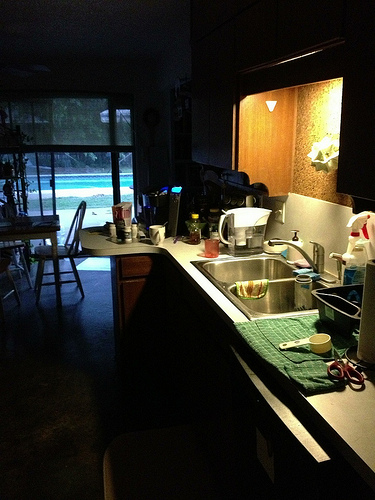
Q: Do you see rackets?
A: No, there are no rackets.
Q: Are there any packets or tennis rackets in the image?
A: No, there are no tennis rackets or packets.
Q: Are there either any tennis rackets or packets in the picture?
A: No, there are no tennis rackets or packets.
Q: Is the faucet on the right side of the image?
A: Yes, the faucet is on the right of the image.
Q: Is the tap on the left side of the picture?
A: No, the tap is on the right of the image.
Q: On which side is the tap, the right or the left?
A: The tap is on the right of the image.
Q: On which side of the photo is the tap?
A: The tap is on the right of the image.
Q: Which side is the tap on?
A: The tap is on the right of the image.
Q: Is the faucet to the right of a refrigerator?
A: No, the faucet is to the right of the cup.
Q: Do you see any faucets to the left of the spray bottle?
A: Yes, there is a faucet to the left of the spray bottle.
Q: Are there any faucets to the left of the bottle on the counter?
A: Yes, there is a faucet to the left of the spray bottle.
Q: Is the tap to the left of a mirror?
A: No, the tap is to the left of the spray bottle.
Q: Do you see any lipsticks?
A: No, there are no lipsticks.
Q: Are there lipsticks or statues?
A: No, there are no lipsticks or statues.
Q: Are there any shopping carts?
A: No, there are no shopping carts.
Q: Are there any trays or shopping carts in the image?
A: No, there are no shopping carts or trays.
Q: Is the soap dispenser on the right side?
A: Yes, the soap dispenser is on the right of the image.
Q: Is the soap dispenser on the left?
A: No, the soap dispenser is on the right of the image.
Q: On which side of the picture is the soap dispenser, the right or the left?
A: The soap dispenser is on the right of the image.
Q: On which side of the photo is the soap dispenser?
A: The soap dispenser is on the right of the image.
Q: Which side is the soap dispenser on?
A: The soap dispenser is on the right of the image.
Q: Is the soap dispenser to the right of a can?
A: No, the soap dispenser is to the right of the cup.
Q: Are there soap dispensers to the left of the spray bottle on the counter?
A: Yes, there is a soap dispenser to the left of the spray bottle.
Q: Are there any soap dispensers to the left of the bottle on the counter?
A: Yes, there is a soap dispenser to the left of the spray bottle.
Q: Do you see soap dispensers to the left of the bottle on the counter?
A: Yes, there is a soap dispenser to the left of the spray bottle.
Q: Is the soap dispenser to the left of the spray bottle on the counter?
A: Yes, the soap dispenser is to the left of the spray bottle.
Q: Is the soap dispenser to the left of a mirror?
A: No, the soap dispenser is to the left of the spray bottle.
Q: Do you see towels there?
A: Yes, there is a towel.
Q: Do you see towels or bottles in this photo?
A: Yes, there is a towel.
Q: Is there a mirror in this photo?
A: No, there are no mirrors.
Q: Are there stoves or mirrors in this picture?
A: No, there are no mirrors or stoves.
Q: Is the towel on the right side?
A: Yes, the towel is on the right of the image.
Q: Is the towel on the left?
A: No, the towel is on the right of the image.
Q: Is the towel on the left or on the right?
A: The towel is on the right of the image.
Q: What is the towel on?
A: The towel is on the counter.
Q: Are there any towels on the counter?
A: Yes, there is a towel on the counter.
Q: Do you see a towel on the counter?
A: Yes, there is a towel on the counter.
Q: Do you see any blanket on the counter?
A: No, there is a towel on the counter.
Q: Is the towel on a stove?
A: No, the towel is on a counter.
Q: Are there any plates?
A: No, there are no plates.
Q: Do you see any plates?
A: No, there are no plates.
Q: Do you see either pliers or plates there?
A: No, there are no plates or pliers.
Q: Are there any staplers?
A: No, there are no staplers.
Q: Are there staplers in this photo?
A: No, there are no staplers.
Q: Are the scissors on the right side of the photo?
A: Yes, the scissors are on the right of the image.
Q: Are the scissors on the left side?
A: No, the scissors are on the right of the image.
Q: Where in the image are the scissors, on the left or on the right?
A: The scissors are on the right of the image.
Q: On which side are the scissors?
A: The scissors are on the right of the image.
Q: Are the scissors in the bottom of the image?
A: Yes, the scissors are in the bottom of the image.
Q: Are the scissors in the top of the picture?
A: No, the scissors are in the bottom of the image.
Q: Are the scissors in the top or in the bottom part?
A: The scissors are in the bottom of the image.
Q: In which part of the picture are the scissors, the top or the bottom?
A: The scissors are in the bottom of the image.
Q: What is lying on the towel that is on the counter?
A: The scissors are lying on the towel.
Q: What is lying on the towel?
A: The scissors are lying on the towel.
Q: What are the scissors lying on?
A: The scissors are lying on the towel.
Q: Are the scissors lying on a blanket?
A: No, the scissors are lying on the towel.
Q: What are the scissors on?
A: The scissors are on the counter.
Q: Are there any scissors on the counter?
A: Yes, there are scissors on the counter.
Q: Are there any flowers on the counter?
A: No, there are scissors on the counter.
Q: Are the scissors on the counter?
A: Yes, the scissors are on the counter.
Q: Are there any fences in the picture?
A: No, there are no fences.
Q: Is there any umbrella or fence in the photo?
A: No, there are no fences or umbrellas.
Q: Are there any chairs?
A: Yes, there is a chair.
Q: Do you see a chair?
A: Yes, there is a chair.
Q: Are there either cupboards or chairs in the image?
A: Yes, there is a chair.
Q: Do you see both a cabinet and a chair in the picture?
A: Yes, there are both a chair and a cabinet.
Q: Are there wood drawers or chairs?
A: Yes, there is a wood chair.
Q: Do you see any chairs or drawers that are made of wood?
A: Yes, the chair is made of wood.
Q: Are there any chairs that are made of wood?
A: Yes, there is a chair that is made of wood.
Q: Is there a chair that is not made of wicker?
A: Yes, there is a chair that is made of wood.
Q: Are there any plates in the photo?
A: No, there are no plates.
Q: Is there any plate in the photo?
A: No, there are no plates.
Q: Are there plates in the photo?
A: No, there are no plates.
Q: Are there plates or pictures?
A: No, there are no plates or pictures.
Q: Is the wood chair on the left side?
A: Yes, the chair is on the left of the image.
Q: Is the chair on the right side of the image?
A: No, the chair is on the left of the image.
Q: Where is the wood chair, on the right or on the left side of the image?
A: The chair is on the left of the image.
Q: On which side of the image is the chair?
A: The chair is on the left of the image.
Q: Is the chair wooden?
A: Yes, the chair is wooden.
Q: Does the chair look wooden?
A: Yes, the chair is wooden.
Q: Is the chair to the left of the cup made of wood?
A: Yes, the chair is made of wood.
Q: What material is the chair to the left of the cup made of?
A: The chair is made of wood.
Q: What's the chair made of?
A: The chair is made of wood.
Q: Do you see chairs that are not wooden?
A: No, there is a chair but it is wooden.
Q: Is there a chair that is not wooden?
A: No, there is a chair but it is wooden.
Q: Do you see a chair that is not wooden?
A: No, there is a chair but it is wooden.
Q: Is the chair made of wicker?
A: No, the chair is made of wood.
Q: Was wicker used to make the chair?
A: No, the chair is made of wood.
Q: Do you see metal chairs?
A: No, there is a chair but it is made of wood.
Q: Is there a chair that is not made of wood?
A: No, there is a chair but it is made of wood.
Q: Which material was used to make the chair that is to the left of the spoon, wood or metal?
A: The chair is made of wood.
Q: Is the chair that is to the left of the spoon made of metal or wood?
A: The chair is made of wood.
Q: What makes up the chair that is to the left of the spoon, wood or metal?
A: The chair is made of wood.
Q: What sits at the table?
A: The chair sits at the table.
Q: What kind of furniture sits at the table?
A: The piece of furniture is a chair.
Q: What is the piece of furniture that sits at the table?
A: The piece of furniture is a chair.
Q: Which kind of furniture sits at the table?
A: The piece of furniture is a chair.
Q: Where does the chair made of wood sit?
A: The chair sits at the table.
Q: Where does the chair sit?
A: The chair sits at the table.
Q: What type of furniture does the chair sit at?
A: The chair sits at the table.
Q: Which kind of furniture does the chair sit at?
A: The chair sits at the table.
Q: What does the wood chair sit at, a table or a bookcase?
A: The chair sits at a table.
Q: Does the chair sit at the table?
A: Yes, the chair sits at the table.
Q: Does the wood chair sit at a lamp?
A: No, the chair sits at the table.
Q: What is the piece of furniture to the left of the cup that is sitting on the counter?
A: The piece of furniture is a chair.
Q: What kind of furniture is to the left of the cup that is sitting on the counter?
A: The piece of furniture is a chair.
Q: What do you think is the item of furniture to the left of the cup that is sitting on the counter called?
A: The piece of furniture is a chair.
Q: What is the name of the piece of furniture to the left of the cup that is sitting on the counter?
A: The piece of furniture is a chair.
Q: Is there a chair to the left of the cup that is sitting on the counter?
A: Yes, there is a chair to the left of the cup.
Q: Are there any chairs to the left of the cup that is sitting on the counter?
A: Yes, there is a chair to the left of the cup.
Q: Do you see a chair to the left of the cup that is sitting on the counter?
A: Yes, there is a chair to the left of the cup.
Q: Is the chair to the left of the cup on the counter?
A: Yes, the chair is to the left of the cup.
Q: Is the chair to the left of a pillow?
A: No, the chair is to the left of the cup.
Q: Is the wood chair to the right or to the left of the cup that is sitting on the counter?
A: The chair is to the left of the cup.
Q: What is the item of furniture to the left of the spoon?
A: The piece of furniture is a chair.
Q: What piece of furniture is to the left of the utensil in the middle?
A: The piece of furniture is a chair.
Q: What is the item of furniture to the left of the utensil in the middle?
A: The piece of furniture is a chair.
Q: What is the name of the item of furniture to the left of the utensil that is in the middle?
A: The piece of furniture is a chair.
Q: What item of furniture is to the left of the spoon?
A: The piece of furniture is a chair.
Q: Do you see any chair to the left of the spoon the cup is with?
A: Yes, there is a chair to the left of the spoon.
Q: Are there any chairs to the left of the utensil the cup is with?
A: Yes, there is a chair to the left of the spoon.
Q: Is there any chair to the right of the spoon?
A: No, the chair is to the left of the spoon.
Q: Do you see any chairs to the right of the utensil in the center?
A: No, the chair is to the left of the spoon.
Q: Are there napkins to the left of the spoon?
A: No, there is a chair to the left of the spoon.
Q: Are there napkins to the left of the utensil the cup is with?
A: No, there is a chair to the left of the spoon.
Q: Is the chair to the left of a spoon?
A: Yes, the chair is to the left of a spoon.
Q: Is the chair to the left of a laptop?
A: No, the chair is to the left of a spoon.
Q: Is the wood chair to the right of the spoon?
A: No, the chair is to the left of the spoon.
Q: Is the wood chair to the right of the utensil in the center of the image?
A: No, the chair is to the left of the spoon.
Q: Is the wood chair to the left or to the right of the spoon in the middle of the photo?
A: The chair is to the left of the spoon.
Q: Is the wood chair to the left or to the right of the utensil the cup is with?
A: The chair is to the left of the spoon.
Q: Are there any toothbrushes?
A: No, there are no toothbrushes.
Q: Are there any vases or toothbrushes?
A: No, there are no toothbrushes or vases.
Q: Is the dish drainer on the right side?
A: Yes, the dish drainer is on the right of the image.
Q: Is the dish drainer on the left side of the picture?
A: No, the dish drainer is on the right of the image.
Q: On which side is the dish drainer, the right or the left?
A: The dish drainer is on the right of the image.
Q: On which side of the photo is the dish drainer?
A: The dish drainer is on the right of the image.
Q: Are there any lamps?
A: No, there are no lamps.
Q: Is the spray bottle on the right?
A: Yes, the spray bottle is on the right of the image.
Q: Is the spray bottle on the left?
A: No, the spray bottle is on the right of the image.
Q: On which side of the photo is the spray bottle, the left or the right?
A: The spray bottle is on the right of the image.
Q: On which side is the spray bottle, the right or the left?
A: The spray bottle is on the right of the image.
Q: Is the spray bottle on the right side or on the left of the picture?
A: The spray bottle is on the right of the image.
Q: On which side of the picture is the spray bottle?
A: The spray bottle is on the right of the image.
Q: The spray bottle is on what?
A: The spray bottle is on the counter.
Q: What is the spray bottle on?
A: The spray bottle is on the counter.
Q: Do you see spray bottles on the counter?
A: Yes, there is a spray bottle on the counter.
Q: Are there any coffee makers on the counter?
A: No, there is a spray bottle on the counter.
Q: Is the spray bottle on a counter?
A: Yes, the spray bottle is on a counter.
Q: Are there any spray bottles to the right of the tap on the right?
A: Yes, there is a spray bottle to the right of the tap.